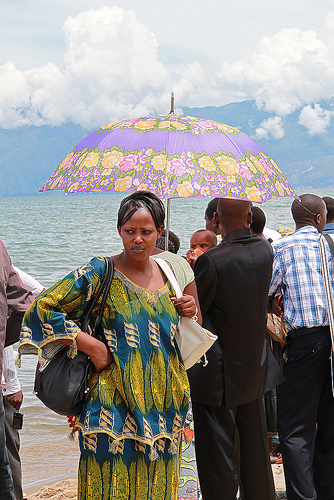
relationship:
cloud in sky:
[0, 62, 30, 111] [1, 3, 333, 139]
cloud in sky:
[30, 59, 65, 130] [1, 3, 333, 139]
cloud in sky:
[108, 14, 331, 98] [1, 3, 333, 139]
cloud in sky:
[252, 113, 286, 145] [1, 3, 333, 139]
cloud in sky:
[229, 24, 330, 99] [1, 3, 333, 139]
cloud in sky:
[0, 70, 44, 125] [5, 9, 65, 62]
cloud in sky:
[108, 14, 331, 98] [1, 1, 330, 188]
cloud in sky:
[108, 14, 331, 98] [2, 3, 332, 110]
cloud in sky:
[295, 101, 331, 142] [6, 3, 327, 99]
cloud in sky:
[252, 113, 286, 145] [2, 3, 332, 110]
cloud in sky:
[252, 113, 286, 145] [193, 33, 308, 107]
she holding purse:
[14, 189, 199, 499] [151, 257, 218, 371]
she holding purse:
[14, 189, 199, 499] [33, 255, 115, 415]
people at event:
[198, 187, 285, 499] [5, 76, 330, 496]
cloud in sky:
[108, 14, 331, 98] [6, 3, 327, 99]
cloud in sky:
[252, 113, 286, 145] [1, 1, 330, 188]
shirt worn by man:
[268, 225, 332, 327] [269, 195, 333, 498]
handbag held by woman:
[33, 255, 114, 416] [17, 187, 209, 496]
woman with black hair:
[17, 187, 209, 496] [117, 190, 165, 228]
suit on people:
[189, 225, 279, 495] [198, 187, 273, 500]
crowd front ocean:
[0, 189, 331, 496] [1, 188, 332, 289]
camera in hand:
[9, 408, 24, 430] [1, 387, 23, 411]